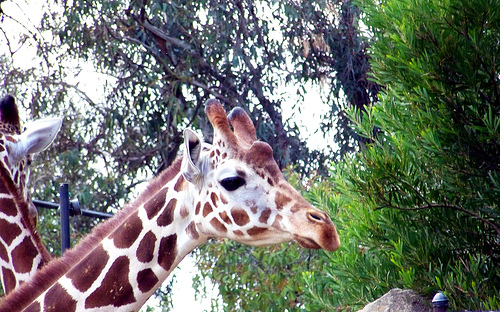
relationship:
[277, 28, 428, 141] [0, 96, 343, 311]
trees behind giraffe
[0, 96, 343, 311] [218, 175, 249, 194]
giraffe has eye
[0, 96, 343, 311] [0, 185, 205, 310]
giraffe has neck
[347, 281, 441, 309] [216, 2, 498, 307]
rock under tree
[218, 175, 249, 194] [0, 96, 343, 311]
eye on giraffe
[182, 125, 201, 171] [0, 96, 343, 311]
ear on giraffe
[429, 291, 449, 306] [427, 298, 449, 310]
hat on head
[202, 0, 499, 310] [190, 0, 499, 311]
leaves on tree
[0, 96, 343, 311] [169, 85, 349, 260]
giraffe has head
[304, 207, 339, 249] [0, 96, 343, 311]
nose belonging to giraffe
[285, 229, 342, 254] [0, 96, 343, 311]
mouth belonging to giraffe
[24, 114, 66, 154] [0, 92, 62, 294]
ear belonging to giraffe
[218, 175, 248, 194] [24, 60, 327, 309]
eye belonging to giraffe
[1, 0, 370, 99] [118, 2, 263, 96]
sky through trees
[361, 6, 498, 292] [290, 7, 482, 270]
leaves on tree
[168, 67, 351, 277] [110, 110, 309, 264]
face of giraffe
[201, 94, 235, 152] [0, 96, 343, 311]
horn on side of giraffe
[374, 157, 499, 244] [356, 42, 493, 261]
sticks on trees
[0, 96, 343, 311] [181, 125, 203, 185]
giraffe has ear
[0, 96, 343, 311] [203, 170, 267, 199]
giraffe has eye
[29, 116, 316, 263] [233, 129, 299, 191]
giraffe has forehead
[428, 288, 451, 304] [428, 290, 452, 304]
top has top